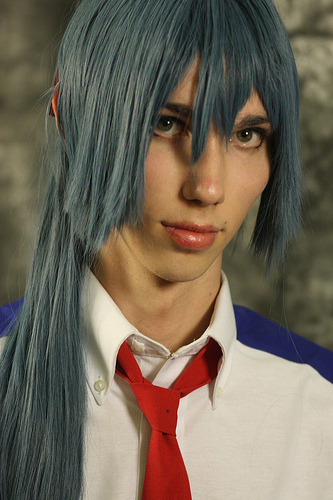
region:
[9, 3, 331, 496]
this is a person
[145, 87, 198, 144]
this is a person's eye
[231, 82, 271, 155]
this is a person's eye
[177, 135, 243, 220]
this is a person's nose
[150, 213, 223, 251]
this is a person's mouth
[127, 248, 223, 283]
this is a person's chin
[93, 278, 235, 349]
this is a person's neck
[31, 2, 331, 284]
this is a person's head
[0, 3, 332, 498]
this is a person's hair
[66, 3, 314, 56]
this is black hair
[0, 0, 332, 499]
androgynous person dressed in costume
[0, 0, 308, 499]
long asymmetrical grey wig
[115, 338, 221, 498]
red neck tie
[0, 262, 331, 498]
blue and white button up shirt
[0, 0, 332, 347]
grey mottled background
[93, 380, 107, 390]
small clear collar button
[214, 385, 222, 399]
small clear collar button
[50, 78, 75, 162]
persons ear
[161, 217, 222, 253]
persons full lips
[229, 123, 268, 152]
persons green eye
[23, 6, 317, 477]
a guy with bluish colored hair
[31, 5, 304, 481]
a guy wearing an orange tie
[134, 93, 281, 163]
a guy wearing eyeliner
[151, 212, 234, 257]
the lips of a young man